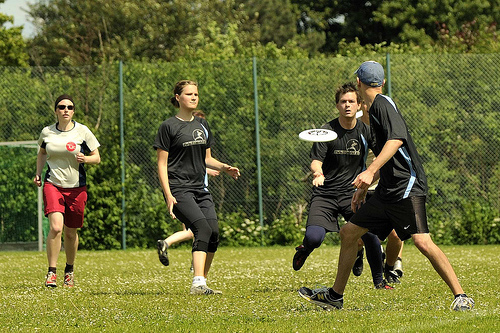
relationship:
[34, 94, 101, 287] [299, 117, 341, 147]
female playing frisbee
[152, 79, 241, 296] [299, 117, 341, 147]
female playing frisbee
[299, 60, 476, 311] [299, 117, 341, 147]
guy playing frisbee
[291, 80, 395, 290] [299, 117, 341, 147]
male playing frisbee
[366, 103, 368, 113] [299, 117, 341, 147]
man playing frisbee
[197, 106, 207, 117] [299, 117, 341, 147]
man playing frisbee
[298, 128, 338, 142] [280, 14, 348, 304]
frisbee thrown mid air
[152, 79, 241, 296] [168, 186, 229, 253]
female wearing leggings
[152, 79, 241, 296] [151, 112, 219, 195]
female wearing shirt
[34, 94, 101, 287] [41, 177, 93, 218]
female wearing shorts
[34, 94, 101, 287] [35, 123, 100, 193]
female wears shirt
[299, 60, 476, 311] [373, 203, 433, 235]
guy wears shorts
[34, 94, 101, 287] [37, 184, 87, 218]
female wears shorts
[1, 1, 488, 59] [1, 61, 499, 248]
trees behind fence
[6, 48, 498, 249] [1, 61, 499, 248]
bushes behind fence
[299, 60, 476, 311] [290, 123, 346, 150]
guy plays frisbee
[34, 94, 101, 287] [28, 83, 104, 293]
female wears sunglasses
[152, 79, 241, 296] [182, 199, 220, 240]
female wears knee bands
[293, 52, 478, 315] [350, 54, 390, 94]
guy wears cap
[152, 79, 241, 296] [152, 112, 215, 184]
female wears shirt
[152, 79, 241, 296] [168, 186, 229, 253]
female wears leggings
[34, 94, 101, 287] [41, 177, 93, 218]
female wears shorts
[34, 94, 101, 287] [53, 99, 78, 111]
female wears sunglasses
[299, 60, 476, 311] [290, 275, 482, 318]
guy wears sneakers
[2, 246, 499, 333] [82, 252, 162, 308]
flowers on grass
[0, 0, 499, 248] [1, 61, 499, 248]
bushes behind fence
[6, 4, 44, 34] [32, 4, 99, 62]
sky behind bushes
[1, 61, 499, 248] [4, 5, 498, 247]
fence in front of bushes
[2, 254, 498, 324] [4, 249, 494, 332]
flowers growing on top of grass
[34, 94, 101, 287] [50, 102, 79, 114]
female in sunglasses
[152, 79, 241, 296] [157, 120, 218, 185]
female in shirt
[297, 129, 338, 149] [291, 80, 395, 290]
frisbee headed towards male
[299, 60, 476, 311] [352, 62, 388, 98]
guy turning h head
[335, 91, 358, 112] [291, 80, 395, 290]
head of a male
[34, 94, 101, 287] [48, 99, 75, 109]
female wearing sunglasses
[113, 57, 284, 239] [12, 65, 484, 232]
poles are attached to fence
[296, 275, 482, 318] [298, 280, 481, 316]
laces are attached to shoes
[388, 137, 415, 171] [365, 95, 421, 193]
stripe attached to shirt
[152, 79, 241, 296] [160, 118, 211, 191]
female wearing shirt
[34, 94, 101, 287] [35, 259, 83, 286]
female wearing sneakers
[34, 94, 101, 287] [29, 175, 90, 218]
female wearing shorts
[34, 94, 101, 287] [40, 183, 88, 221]
female running shorts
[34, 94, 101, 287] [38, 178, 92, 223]
female wearing shorts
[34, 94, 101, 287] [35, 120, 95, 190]
female wearing shirt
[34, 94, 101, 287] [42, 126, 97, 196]
female wearing shirt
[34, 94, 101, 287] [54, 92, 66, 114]
female wearing sunglasses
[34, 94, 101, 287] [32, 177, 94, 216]
female wearing shorts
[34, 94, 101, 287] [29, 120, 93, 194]
female wearing shirt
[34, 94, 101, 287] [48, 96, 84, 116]
female wearing sunglasses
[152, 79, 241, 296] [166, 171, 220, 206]
female wearing shorts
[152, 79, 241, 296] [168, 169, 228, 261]
female wearing leggings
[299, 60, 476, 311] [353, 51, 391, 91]
guy wearing cap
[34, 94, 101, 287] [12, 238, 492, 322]
female are running on field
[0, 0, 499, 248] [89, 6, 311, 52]
bushes are growing on tree